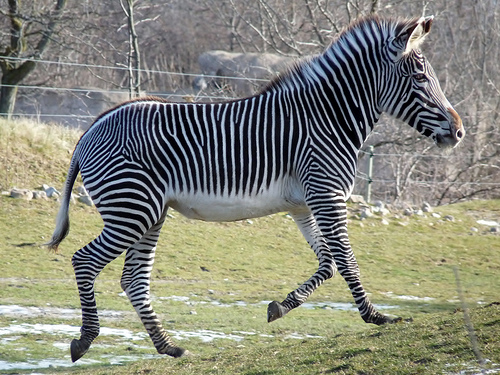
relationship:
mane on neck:
[262, 24, 404, 92] [275, 53, 388, 145]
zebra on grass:
[49, 16, 464, 356] [2, 198, 490, 372]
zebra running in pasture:
[45, 15, 466, 363] [2, 120, 496, 372]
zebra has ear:
[45, 15, 466, 363] [399, 14, 434, 54]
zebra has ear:
[45, 15, 466, 363] [416, 12, 436, 47]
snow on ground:
[168, 318, 260, 358] [146, 290, 329, 374]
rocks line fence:
[348, 192, 443, 228] [3, 52, 498, 207]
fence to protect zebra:
[0, 56, 500, 209] [45, 15, 466, 363]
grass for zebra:
[2, 117, 499, 373] [45, 15, 466, 363]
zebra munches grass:
[45, 15, 466, 363] [2, 117, 499, 373]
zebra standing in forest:
[45, 15, 466, 363] [1, 2, 498, 204]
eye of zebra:
[408, 71, 433, 86] [45, 15, 466, 363]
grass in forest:
[2, 117, 499, 373] [3, 2, 484, 372]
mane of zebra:
[262, 15, 410, 92] [45, 15, 466, 363]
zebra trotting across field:
[45, 15, 466, 363] [0, 116, 497, 373]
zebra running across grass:
[45, 15, 466, 363] [2, 117, 499, 373]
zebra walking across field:
[45, 15, 466, 363] [0, 116, 497, 373]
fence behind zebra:
[16, 45, 481, 217] [45, 15, 466, 363]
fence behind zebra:
[0, 56, 500, 209] [45, 15, 466, 363]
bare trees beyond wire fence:
[11, 11, 211, 67] [2, 82, 50, 129]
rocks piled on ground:
[349, 192, 417, 236] [4, 100, 484, 373]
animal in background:
[191, 49, 319, 98] [6, 2, 497, 143]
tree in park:
[129, 0, 144, 99] [2, 1, 498, 370]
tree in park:
[120, 5, 159, 101] [2, 1, 498, 370]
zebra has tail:
[45, 15, 466, 363] [45, 150, 81, 251]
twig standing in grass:
[433, 252, 493, 373] [2, 117, 499, 373]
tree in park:
[2, 0, 67, 119] [392, 228, 486, 327]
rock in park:
[34, 69, 108, 117] [2, 93, 484, 357]